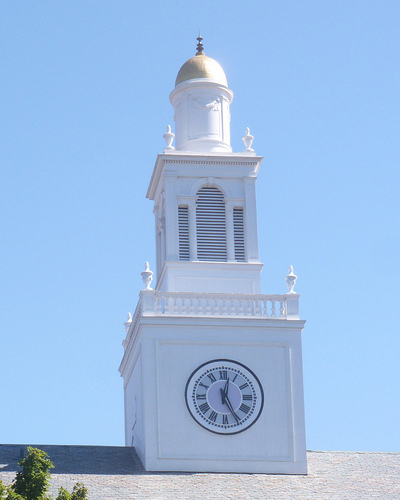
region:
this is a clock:
[187, 353, 264, 437]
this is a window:
[176, 208, 189, 255]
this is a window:
[195, 188, 225, 260]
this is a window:
[230, 205, 250, 262]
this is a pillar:
[190, 202, 204, 258]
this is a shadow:
[75, 448, 130, 470]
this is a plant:
[20, 452, 53, 499]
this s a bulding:
[111, 38, 313, 473]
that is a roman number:
[202, 371, 216, 384]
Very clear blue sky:
[0, 0, 399, 453]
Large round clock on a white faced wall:
[179, 351, 269, 439]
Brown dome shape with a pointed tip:
[168, 24, 232, 97]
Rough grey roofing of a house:
[0, 443, 398, 499]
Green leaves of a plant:
[1, 443, 90, 499]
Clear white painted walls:
[105, 77, 326, 475]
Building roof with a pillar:
[0, 0, 399, 499]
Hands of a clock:
[219, 374, 244, 427]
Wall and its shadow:
[0, 340, 152, 478]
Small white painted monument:
[279, 262, 302, 296]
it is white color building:
[114, 31, 318, 478]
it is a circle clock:
[185, 355, 265, 435]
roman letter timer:
[194, 365, 256, 426]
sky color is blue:
[18, 18, 102, 326]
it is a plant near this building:
[0, 444, 88, 497]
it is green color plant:
[0, 446, 68, 499]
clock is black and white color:
[175, 357, 268, 434]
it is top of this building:
[142, 32, 238, 94]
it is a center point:
[209, 383, 238, 412]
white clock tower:
[115, 31, 319, 476]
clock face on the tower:
[185, 356, 263, 432]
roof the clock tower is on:
[1, 440, 394, 499]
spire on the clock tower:
[192, 33, 206, 54]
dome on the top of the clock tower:
[173, 55, 227, 81]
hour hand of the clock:
[221, 376, 231, 392]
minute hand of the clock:
[221, 395, 238, 419]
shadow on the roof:
[4, 441, 145, 476]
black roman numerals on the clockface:
[193, 367, 255, 424]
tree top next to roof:
[1, 444, 81, 498]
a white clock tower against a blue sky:
[91, 11, 337, 489]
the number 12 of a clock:
[216, 367, 230, 381]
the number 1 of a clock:
[229, 372, 240, 383]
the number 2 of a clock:
[236, 379, 253, 391]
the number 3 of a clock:
[240, 391, 254, 402]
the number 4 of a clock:
[236, 403, 253, 416]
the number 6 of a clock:
[219, 412, 231, 426]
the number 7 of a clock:
[207, 409, 219, 423]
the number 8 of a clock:
[196, 400, 209, 416]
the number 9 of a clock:
[191, 389, 210, 402]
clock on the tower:
[173, 344, 271, 443]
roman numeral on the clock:
[216, 368, 228, 384]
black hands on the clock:
[215, 376, 236, 419]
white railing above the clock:
[142, 292, 282, 317]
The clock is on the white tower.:
[117, 28, 308, 474]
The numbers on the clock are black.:
[183, 357, 265, 434]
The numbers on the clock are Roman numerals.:
[183, 358, 265, 436]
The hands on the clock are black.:
[183, 357, 265, 436]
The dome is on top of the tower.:
[113, 31, 310, 477]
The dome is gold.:
[170, 30, 228, 84]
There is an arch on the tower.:
[117, 31, 307, 475]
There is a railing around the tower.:
[114, 29, 311, 475]